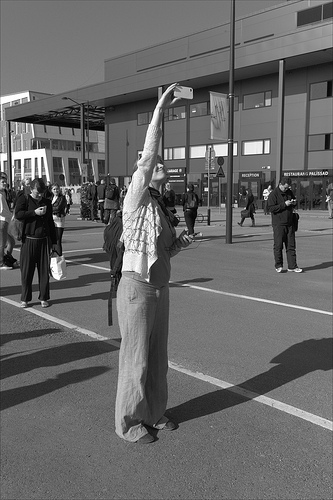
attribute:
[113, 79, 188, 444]
person — photographing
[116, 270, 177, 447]
pants — linen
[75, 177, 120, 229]
people — grouped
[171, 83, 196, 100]
phone — white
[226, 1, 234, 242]
pole — metal, tall, big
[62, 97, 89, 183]
street light — black, here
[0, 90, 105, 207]
building — large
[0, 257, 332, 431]
stripes — painted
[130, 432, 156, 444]
shoe — here